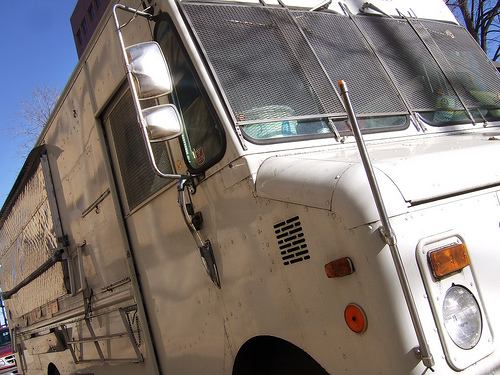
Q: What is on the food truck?
A: A windshield.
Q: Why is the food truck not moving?
A: It is out of service.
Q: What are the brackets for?
A: Holding the pole.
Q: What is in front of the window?
A: A windscreen.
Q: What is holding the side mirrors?
A: A bracket.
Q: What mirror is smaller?
A: The lower one.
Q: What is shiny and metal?
A: The metal mirror.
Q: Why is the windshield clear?
A: To see through it.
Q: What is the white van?
A: Large.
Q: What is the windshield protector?
A: Metal screen.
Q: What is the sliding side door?
A: White.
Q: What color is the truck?
A: White.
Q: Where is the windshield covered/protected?
A: On the Front.